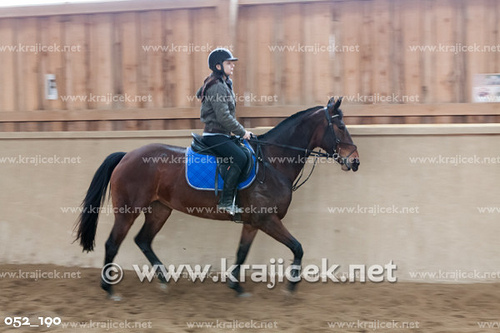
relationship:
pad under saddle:
[182, 135, 264, 195] [185, 127, 252, 155]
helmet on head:
[206, 47, 236, 66] [206, 47, 239, 77]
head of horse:
[301, 99, 369, 169] [84, 90, 347, 278]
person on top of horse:
[193, 46, 251, 216] [75, 93, 359, 293]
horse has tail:
[75, 93, 359, 293] [70, 144, 119, 254]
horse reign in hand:
[242, 129, 332, 159] [242, 130, 254, 138]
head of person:
[204, 50, 236, 78] [197, 47, 257, 206]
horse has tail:
[75, 93, 359, 293] [72, 149, 125, 253]